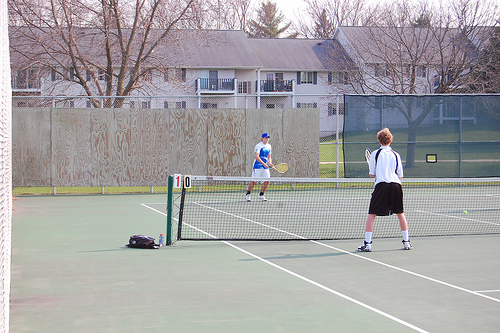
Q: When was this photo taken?
A: Daytime.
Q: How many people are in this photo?
A: Two.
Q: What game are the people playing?
A: Tennis.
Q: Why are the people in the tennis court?
A: Play tennis.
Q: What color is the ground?
A: Green.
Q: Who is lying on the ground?
A: No one.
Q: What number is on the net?
A: 10.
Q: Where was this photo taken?
A: At the tennis courts.